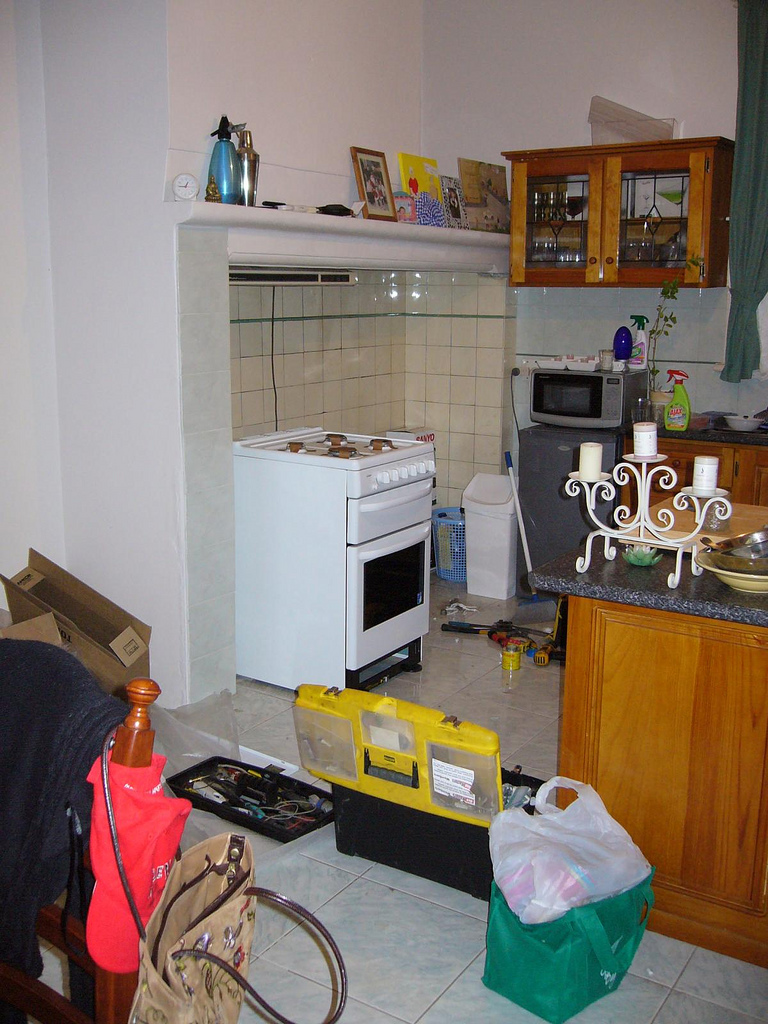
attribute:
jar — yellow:
[493, 640, 528, 677]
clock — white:
[164, 162, 200, 206]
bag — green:
[477, 878, 649, 1006]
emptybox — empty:
[5, 541, 165, 701]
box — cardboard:
[6, 534, 156, 707]